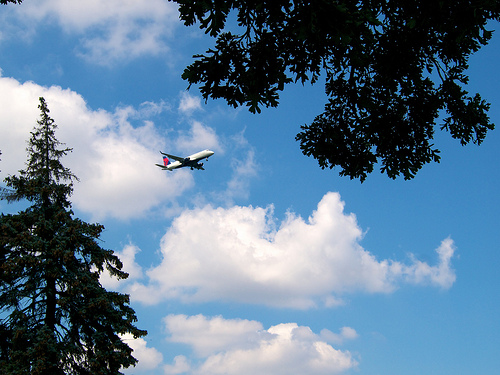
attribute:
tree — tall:
[9, 74, 149, 372]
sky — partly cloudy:
[61, 77, 466, 362]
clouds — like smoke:
[0, 0, 460, 374]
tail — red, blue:
[155, 151, 175, 166]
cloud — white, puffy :
[145, 182, 465, 309]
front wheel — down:
[202, 156, 209, 162]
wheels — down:
[187, 165, 202, 175]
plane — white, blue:
[157, 148, 212, 171]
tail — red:
[154, 153, 171, 169]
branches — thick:
[24, 284, 86, 374]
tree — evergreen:
[3, 91, 118, 368]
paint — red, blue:
[162, 155, 167, 165]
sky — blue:
[1, 0, 499, 372]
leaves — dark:
[193, 52, 492, 184]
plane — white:
[153, 147, 214, 173]